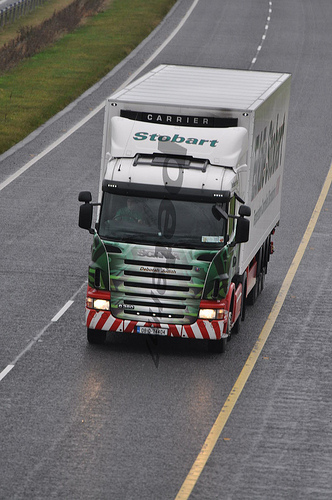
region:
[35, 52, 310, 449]
A truck on the road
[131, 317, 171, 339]
A white license plate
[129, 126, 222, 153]
The word "Stobart" on a truck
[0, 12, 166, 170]
Grass on side of the road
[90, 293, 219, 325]
Two headlights are on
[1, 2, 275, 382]
White lines on the road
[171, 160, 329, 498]
Yellow line on the road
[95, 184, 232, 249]
Front window of a truck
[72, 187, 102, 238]
A black side mirror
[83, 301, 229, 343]
Red and white stripes on the truck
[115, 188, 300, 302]
This is a window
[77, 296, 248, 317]
the light is yellow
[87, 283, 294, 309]
the lights are white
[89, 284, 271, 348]
these are two lights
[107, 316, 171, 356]
this is a plate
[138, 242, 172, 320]
this is a vent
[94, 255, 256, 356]
this is a truck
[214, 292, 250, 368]
this is a wheel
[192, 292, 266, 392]
the wheel is black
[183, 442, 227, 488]
the line is yellow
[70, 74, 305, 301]
a truck is on the road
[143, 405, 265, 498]
a yellow line is on the road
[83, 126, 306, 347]
the truck is the only vehicle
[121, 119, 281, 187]
green print is on the truck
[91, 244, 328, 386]
the truck has a colorful grill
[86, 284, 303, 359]
the bumber is red and white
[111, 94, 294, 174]
black logo is on the truck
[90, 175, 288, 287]
a large window is on the truck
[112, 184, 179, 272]
one man is driving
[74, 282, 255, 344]
two lights are on the truck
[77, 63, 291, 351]
the large truck on the road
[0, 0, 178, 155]
the grass near the road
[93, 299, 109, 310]
the light on the truck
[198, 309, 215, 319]
the light on the truck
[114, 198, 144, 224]
the drive in the truck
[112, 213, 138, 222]
the steering wheel in the truck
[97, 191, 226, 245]
the windshield on the truck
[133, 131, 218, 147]
the word "Stobart"on the truck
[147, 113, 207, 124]
the word "CARRIER" on the truck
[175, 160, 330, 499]
the yellow line on the road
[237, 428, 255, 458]
edge of a road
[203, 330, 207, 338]
part of a truck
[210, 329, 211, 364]
part of a light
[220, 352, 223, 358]
part of a wheel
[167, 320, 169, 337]
edge of a wheel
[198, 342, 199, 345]
part of a truck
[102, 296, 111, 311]
part of a light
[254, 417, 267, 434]
edge of a road